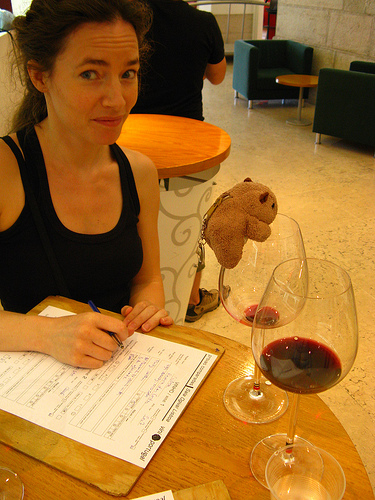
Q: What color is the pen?
A: Blue.